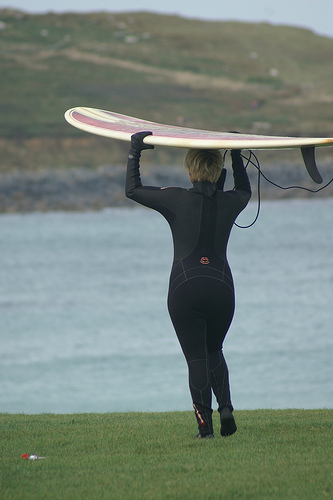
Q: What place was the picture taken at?
A: It was taken at the ocean.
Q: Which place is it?
A: It is an ocean.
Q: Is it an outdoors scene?
A: Yes, it is outdoors.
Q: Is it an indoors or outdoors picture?
A: It is outdoors.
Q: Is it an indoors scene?
A: No, it is outdoors.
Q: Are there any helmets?
A: No, there are no helmets.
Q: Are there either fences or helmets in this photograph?
A: No, there are no helmets or fences.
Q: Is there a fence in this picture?
A: No, there are no fences.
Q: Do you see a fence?
A: No, there are no fences.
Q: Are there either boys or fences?
A: No, there are no fences or boys.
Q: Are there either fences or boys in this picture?
A: No, there are no fences or boys.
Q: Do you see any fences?
A: No, there are no fences.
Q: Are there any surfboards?
A: Yes, there is a surfboard.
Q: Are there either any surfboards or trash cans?
A: Yes, there is a surfboard.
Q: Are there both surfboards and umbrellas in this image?
A: No, there is a surfboard but no umbrellas.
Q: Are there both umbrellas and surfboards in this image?
A: No, there is a surfboard but no umbrellas.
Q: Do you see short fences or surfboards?
A: Yes, there is a short surfboard.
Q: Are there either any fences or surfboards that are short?
A: Yes, the surfboard is short.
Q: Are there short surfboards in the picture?
A: Yes, there is a short surfboard.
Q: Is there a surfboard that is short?
A: Yes, there is a surfboard that is short.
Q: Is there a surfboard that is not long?
A: Yes, there is a short surfboard.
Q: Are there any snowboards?
A: No, there are no snowboards.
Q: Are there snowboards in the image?
A: No, there are no snowboards.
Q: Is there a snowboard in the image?
A: No, there are no snowboards.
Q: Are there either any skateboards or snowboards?
A: No, there are no snowboards or skateboards.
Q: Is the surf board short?
A: Yes, the surf board is short.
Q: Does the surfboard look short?
A: Yes, the surfboard is short.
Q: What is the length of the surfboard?
A: The surfboard is short.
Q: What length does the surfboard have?
A: The surfboard has short length.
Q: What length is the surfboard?
A: The surfboard is short.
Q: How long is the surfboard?
A: The surfboard is short.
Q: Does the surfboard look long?
A: No, the surfboard is short.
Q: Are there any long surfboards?
A: No, there is a surfboard but it is short.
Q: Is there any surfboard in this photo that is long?
A: No, there is a surfboard but it is short.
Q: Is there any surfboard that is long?
A: No, there is a surfboard but it is short.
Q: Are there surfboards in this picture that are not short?
A: No, there is a surfboard but it is short.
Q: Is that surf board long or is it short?
A: The surf board is short.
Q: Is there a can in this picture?
A: No, there are no cans.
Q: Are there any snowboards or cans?
A: No, there are no cans or snowboards.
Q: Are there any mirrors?
A: No, there are no mirrors.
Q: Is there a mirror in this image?
A: No, there are no mirrors.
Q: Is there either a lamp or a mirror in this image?
A: No, there are no mirrors or lamps.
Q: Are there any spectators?
A: No, there are no spectators.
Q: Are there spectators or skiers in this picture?
A: No, there are no spectators or skiers.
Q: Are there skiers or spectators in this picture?
A: No, there are no spectators or skiers.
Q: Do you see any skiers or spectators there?
A: No, there are no spectators or skiers.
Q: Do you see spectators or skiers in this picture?
A: No, there are no spectators or skiers.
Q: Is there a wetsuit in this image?
A: Yes, there is a wetsuit.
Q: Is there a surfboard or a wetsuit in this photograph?
A: Yes, there is a wetsuit.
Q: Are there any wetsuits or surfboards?
A: Yes, there is a wetsuit.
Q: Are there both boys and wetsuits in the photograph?
A: No, there is a wetsuit but no boys.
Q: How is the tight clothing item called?
A: The clothing item is a wetsuit.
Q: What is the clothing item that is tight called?
A: The clothing item is a wetsuit.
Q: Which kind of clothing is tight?
A: The clothing is a wetsuit.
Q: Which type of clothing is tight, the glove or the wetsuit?
A: The wetsuit is tight.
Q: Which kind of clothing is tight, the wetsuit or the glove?
A: The wetsuit is tight.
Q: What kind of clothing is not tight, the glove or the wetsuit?
A: The glove is not tight.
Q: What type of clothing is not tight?
A: The clothing is a glove.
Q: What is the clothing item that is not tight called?
A: The clothing item is a glove.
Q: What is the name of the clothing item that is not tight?
A: The clothing item is a glove.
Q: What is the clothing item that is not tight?
A: The clothing item is a glove.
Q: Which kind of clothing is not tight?
A: The clothing is a glove.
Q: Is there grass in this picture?
A: Yes, there is grass.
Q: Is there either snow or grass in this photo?
A: Yes, there is grass.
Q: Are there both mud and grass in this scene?
A: No, there is grass but no mud.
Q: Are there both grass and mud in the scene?
A: No, there is grass but no mud.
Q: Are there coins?
A: No, there are no coins.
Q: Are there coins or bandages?
A: No, there are no coins or bandages.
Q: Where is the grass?
A: The grass is on the ground.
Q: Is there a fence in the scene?
A: No, there are no fences.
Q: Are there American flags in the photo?
A: No, there are no American flags.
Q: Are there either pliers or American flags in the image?
A: No, there are no American flags or pliers.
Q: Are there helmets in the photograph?
A: No, there are no helmets.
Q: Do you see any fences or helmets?
A: No, there are no helmets or fences.